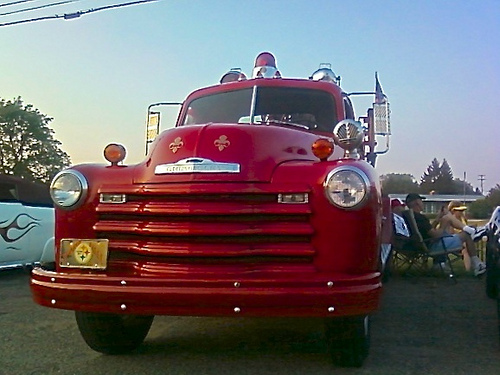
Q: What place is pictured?
A: It is a pavement.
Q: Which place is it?
A: It is a pavement.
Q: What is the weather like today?
A: It is clear.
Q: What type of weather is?
A: It is clear.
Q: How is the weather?
A: It is clear.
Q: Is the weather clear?
A: Yes, it is clear.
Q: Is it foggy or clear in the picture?
A: It is clear.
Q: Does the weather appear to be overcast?
A: No, it is clear.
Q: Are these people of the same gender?
A: No, they are both male and female.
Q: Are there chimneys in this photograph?
A: No, there are no chimneys.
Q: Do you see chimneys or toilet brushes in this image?
A: No, there are no chimneys or toilet brushes.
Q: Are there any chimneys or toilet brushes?
A: No, there are no chimneys or toilet brushes.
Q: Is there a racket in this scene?
A: No, there are no rackets.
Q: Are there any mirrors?
A: Yes, there is a mirror.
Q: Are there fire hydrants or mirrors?
A: Yes, there is a mirror.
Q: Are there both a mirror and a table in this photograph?
A: No, there is a mirror but no tables.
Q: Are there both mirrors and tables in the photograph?
A: No, there is a mirror but no tables.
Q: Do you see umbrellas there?
A: No, there are no umbrellas.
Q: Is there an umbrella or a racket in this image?
A: No, there are no umbrellas or rackets.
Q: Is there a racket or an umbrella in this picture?
A: No, there are no umbrellas or rackets.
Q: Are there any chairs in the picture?
A: Yes, there is a chair.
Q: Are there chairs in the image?
A: Yes, there is a chair.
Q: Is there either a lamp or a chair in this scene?
A: Yes, there is a chair.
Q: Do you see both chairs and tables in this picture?
A: No, there is a chair but no tables.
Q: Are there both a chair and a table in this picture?
A: No, there is a chair but no tables.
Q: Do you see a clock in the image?
A: No, there are no clocks.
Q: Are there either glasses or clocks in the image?
A: No, there are no clocks or glasses.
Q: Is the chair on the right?
A: Yes, the chair is on the right of the image.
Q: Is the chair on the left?
A: No, the chair is on the right of the image.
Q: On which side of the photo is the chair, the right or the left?
A: The chair is on the right of the image.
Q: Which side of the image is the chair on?
A: The chair is on the right of the image.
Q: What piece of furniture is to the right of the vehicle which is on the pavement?
A: The piece of furniture is a chair.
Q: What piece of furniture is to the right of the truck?
A: The piece of furniture is a chair.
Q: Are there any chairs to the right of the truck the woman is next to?
A: Yes, there is a chair to the right of the truck.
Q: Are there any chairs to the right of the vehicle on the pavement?
A: Yes, there is a chair to the right of the truck.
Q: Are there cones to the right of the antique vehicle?
A: No, there is a chair to the right of the truck.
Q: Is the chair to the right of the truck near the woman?
A: Yes, the chair is to the right of the truck.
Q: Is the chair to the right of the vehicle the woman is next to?
A: Yes, the chair is to the right of the truck.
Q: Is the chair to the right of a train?
A: No, the chair is to the right of the truck.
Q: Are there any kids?
A: No, there are no kids.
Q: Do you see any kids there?
A: No, there are no kids.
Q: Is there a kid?
A: No, there are no children.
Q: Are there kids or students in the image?
A: No, there are no kids or students.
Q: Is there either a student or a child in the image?
A: No, there are no children or students.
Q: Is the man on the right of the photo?
A: Yes, the man is on the right of the image.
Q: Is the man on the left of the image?
A: No, the man is on the right of the image.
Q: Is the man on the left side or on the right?
A: The man is on the right of the image.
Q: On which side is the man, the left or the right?
A: The man is on the right of the image.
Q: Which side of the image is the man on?
A: The man is on the right of the image.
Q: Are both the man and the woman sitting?
A: Yes, both the man and the woman are sitting.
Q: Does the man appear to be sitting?
A: Yes, the man is sitting.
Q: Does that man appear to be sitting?
A: Yes, the man is sitting.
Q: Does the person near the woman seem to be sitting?
A: Yes, the man is sitting.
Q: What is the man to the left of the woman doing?
A: The man is sitting.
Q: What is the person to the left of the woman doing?
A: The man is sitting.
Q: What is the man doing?
A: The man is sitting.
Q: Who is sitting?
A: The man is sitting.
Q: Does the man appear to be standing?
A: No, the man is sitting.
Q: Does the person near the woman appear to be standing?
A: No, the man is sitting.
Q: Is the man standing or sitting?
A: The man is sitting.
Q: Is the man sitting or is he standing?
A: The man is sitting.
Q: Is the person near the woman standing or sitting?
A: The man is sitting.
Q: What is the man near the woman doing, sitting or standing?
A: The man is sitting.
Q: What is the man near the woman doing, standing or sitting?
A: The man is sitting.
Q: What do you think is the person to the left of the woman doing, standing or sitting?
A: The man is sitting.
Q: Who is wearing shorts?
A: The man is wearing shorts.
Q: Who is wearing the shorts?
A: The man is wearing shorts.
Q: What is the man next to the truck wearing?
A: The man is wearing shorts.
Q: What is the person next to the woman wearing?
A: The man is wearing shorts.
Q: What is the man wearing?
A: The man is wearing shorts.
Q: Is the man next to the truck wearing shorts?
A: Yes, the man is wearing shorts.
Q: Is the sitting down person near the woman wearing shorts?
A: Yes, the man is wearing shorts.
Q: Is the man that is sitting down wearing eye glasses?
A: No, the man is wearing shorts.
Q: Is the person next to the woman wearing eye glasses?
A: No, the man is wearing shorts.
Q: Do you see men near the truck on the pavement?
A: Yes, there is a man near the truck.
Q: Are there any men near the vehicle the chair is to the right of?
A: Yes, there is a man near the truck.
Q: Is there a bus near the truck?
A: No, there is a man near the truck.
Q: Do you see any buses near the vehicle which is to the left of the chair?
A: No, there is a man near the truck.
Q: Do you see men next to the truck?
A: Yes, there is a man next to the truck.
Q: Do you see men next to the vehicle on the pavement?
A: Yes, there is a man next to the truck.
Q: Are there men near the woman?
A: Yes, there is a man near the woman.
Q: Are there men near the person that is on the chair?
A: Yes, there is a man near the woman.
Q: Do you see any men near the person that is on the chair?
A: Yes, there is a man near the woman.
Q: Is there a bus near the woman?
A: No, there is a man near the woman.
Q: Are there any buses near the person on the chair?
A: No, there is a man near the woman.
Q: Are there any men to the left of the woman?
A: Yes, there is a man to the left of the woman.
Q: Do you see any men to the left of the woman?
A: Yes, there is a man to the left of the woman.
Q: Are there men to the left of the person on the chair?
A: Yes, there is a man to the left of the woman.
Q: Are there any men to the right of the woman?
A: No, the man is to the left of the woman.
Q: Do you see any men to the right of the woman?
A: No, the man is to the left of the woman.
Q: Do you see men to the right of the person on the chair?
A: No, the man is to the left of the woman.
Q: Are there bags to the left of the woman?
A: No, there is a man to the left of the woman.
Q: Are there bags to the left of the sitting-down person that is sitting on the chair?
A: No, there is a man to the left of the woman.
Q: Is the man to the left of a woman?
A: Yes, the man is to the left of a woman.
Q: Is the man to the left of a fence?
A: No, the man is to the left of a woman.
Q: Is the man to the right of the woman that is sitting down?
A: No, the man is to the left of the woman.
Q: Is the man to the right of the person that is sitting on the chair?
A: No, the man is to the left of the woman.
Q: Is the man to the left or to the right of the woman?
A: The man is to the left of the woman.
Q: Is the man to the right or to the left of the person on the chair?
A: The man is to the left of the woman.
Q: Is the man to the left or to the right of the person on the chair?
A: The man is to the left of the woman.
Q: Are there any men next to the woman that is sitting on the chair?
A: Yes, there is a man next to the woman.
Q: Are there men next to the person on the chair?
A: Yes, there is a man next to the woman.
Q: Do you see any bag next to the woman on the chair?
A: No, there is a man next to the woman.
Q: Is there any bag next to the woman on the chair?
A: No, there is a man next to the woman.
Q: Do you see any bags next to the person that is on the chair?
A: No, there is a man next to the woman.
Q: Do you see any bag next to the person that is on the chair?
A: No, there is a man next to the woman.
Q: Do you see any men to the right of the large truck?
A: Yes, there is a man to the right of the truck.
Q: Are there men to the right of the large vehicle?
A: Yes, there is a man to the right of the truck.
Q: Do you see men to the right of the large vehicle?
A: Yes, there is a man to the right of the truck.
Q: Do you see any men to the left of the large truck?
A: No, the man is to the right of the truck.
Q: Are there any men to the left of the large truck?
A: No, the man is to the right of the truck.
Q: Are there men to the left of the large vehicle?
A: No, the man is to the right of the truck.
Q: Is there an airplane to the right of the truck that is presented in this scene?
A: No, there is a man to the right of the truck.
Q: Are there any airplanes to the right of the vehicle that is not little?
A: No, there is a man to the right of the truck.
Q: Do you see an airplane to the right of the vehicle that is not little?
A: No, there is a man to the right of the truck.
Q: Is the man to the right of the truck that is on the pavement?
A: Yes, the man is to the right of the truck.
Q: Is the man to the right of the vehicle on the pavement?
A: Yes, the man is to the right of the truck.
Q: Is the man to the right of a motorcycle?
A: No, the man is to the right of the truck.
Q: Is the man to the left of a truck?
A: No, the man is to the right of a truck.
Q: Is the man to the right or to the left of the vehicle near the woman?
A: The man is to the right of the truck.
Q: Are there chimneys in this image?
A: No, there are no chimneys.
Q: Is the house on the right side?
A: Yes, the house is on the right of the image.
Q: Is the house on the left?
A: No, the house is on the right of the image.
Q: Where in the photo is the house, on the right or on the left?
A: The house is on the right of the image.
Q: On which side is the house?
A: The house is on the right of the image.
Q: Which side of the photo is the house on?
A: The house is on the right of the image.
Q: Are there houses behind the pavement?
A: Yes, there is a house behind the pavement.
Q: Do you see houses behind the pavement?
A: Yes, there is a house behind the pavement.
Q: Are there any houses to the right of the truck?
A: Yes, there is a house to the right of the truck.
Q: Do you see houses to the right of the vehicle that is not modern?
A: Yes, there is a house to the right of the truck.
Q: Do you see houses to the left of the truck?
A: No, the house is to the right of the truck.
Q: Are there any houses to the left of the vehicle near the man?
A: No, the house is to the right of the truck.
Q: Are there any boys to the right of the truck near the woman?
A: No, there is a house to the right of the truck.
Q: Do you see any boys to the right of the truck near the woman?
A: No, there is a house to the right of the truck.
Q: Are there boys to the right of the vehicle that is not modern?
A: No, there is a house to the right of the truck.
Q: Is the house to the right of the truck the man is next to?
A: Yes, the house is to the right of the truck.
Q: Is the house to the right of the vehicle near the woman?
A: Yes, the house is to the right of the truck.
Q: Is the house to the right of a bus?
A: No, the house is to the right of the truck.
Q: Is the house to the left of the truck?
A: No, the house is to the right of the truck.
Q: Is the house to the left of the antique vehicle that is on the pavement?
A: No, the house is to the right of the truck.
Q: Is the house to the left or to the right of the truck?
A: The house is to the right of the truck.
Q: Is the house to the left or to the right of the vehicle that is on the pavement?
A: The house is to the right of the truck.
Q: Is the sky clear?
A: Yes, the sky is clear.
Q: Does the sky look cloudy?
A: No, the sky is clear.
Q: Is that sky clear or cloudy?
A: The sky is clear.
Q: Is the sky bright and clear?
A: Yes, the sky is bright and clear.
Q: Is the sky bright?
A: Yes, the sky is bright.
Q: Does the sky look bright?
A: Yes, the sky is bright.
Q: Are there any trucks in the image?
A: Yes, there is a truck.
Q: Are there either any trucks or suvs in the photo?
A: Yes, there is a truck.